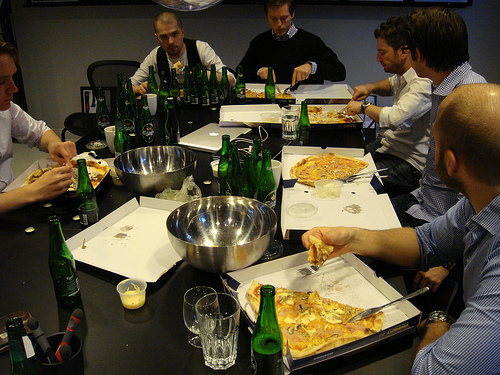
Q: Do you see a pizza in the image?
A: Yes, there is a pizza.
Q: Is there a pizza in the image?
A: Yes, there is a pizza.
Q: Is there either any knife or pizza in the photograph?
A: Yes, there is a pizza.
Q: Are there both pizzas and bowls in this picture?
A: Yes, there are both a pizza and a bowl.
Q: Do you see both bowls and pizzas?
A: Yes, there are both a pizza and a bowl.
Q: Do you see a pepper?
A: No, there are no peppers.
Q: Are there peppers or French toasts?
A: No, there are no peppers or French toasts.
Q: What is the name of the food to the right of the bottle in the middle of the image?
A: The food is a pizza.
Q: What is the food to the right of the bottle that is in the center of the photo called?
A: The food is a pizza.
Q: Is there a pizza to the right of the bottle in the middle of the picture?
A: Yes, there is a pizza to the right of the bottle.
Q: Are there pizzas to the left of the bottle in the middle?
A: No, the pizza is to the right of the bottle.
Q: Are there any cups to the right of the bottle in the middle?
A: No, there is a pizza to the right of the bottle.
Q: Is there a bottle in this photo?
A: Yes, there is a bottle.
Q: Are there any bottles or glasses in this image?
A: Yes, there is a bottle.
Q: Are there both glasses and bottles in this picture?
A: Yes, there are both a bottle and glasses.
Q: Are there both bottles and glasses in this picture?
A: Yes, there are both a bottle and glasses.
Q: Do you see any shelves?
A: No, there are no shelves.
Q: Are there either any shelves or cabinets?
A: No, there are no shelves or cabinets.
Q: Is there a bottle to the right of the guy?
A: Yes, there is a bottle to the right of the guy.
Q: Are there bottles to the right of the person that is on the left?
A: Yes, there is a bottle to the right of the guy.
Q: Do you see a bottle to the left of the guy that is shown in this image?
A: No, the bottle is to the right of the guy.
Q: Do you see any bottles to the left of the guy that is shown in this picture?
A: No, the bottle is to the right of the guy.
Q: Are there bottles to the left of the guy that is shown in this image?
A: No, the bottle is to the right of the guy.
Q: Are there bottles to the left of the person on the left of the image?
A: No, the bottle is to the right of the guy.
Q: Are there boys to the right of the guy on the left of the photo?
A: No, there is a bottle to the right of the guy.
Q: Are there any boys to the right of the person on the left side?
A: No, there is a bottle to the right of the guy.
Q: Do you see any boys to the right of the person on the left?
A: No, there is a bottle to the right of the guy.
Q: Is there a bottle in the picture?
A: Yes, there is a bottle.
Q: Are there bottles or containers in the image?
A: Yes, there is a bottle.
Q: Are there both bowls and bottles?
A: Yes, there are both a bottle and a bowl.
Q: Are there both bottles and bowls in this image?
A: Yes, there are both a bottle and a bowl.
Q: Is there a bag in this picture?
A: No, there are no bags.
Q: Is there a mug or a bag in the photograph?
A: No, there are no bags or mugs.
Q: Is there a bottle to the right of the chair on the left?
A: Yes, there is a bottle to the right of the chair.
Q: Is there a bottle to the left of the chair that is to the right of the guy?
A: No, the bottle is to the right of the chair.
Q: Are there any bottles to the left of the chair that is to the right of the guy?
A: No, the bottle is to the right of the chair.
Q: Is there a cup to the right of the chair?
A: No, there is a bottle to the right of the chair.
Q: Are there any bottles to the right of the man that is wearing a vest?
A: Yes, there is a bottle to the right of the man.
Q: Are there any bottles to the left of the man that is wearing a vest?
A: No, the bottle is to the right of the man.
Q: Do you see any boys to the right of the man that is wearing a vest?
A: No, there is a bottle to the right of the man.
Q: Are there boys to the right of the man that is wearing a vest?
A: No, there is a bottle to the right of the man.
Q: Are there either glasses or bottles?
A: Yes, there is a bottle.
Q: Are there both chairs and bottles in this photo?
A: Yes, there are both a bottle and a chair.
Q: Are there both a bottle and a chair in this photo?
A: Yes, there are both a bottle and a chair.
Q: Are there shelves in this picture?
A: No, there are no shelves.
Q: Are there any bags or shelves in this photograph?
A: No, there are no shelves or bags.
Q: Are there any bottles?
A: Yes, there is a bottle.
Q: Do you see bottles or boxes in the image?
A: Yes, there is a bottle.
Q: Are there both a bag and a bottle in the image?
A: No, there is a bottle but no bags.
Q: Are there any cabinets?
A: No, there are no cabinets.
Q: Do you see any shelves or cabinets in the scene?
A: No, there are no cabinets or shelves.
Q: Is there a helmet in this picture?
A: No, there are no helmets.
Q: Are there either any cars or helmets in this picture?
A: No, there are no helmets or cars.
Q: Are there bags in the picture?
A: No, there are no bags.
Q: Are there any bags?
A: No, there are no bags.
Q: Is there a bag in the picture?
A: No, there are no bags.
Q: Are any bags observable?
A: No, there are no bags.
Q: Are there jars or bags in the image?
A: No, there are no bags or jars.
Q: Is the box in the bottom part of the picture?
A: Yes, the box is in the bottom of the image.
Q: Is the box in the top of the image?
A: No, the box is in the bottom of the image.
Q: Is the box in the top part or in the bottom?
A: The box is in the bottom of the image.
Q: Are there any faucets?
A: No, there are no faucets.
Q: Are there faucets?
A: No, there are no faucets.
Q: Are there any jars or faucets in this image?
A: No, there are no faucets or jars.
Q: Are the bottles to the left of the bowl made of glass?
A: Yes, the bottles are made of glass.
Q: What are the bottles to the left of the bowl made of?
A: The bottles are made of glass.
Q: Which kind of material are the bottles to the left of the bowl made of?
A: The bottles are made of glass.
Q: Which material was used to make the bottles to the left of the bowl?
A: The bottles are made of glass.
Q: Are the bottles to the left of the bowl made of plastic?
A: No, the bottles are made of glass.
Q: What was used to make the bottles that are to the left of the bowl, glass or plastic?
A: The bottles are made of glass.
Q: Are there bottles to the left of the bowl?
A: Yes, there are bottles to the left of the bowl.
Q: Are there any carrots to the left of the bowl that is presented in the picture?
A: No, there are bottles to the left of the bowl.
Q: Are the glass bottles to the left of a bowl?
A: Yes, the bottles are to the left of a bowl.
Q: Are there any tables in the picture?
A: Yes, there is a table.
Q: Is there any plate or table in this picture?
A: Yes, there is a table.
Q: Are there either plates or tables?
A: Yes, there is a table.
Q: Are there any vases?
A: No, there are no vases.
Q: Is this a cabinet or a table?
A: This is a table.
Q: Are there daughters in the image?
A: No, there are no daughters.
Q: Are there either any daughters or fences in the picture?
A: No, there are no daughters or fences.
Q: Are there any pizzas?
A: Yes, there is a pizza.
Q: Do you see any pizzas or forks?
A: Yes, there is a pizza.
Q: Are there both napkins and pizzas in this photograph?
A: No, there is a pizza but no napkins.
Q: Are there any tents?
A: No, there are no tents.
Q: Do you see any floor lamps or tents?
A: No, there are no tents or floor lamps.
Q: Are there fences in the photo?
A: No, there are no fences.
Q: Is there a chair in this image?
A: Yes, there is a chair.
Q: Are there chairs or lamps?
A: Yes, there is a chair.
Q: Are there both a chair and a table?
A: Yes, there are both a chair and a table.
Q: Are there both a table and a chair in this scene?
A: Yes, there are both a chair and a table.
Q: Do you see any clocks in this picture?
A: No, there are no clocks.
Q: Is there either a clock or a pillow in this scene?
A: No, there are no clocks or pillows.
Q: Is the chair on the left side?
A: Yes, the chair is on the left of the image.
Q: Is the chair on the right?
A: No, the chair is on the left of the image.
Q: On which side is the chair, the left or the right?
A: The chair is on the left of the image.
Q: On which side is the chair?
A: The chair is on the left of the image.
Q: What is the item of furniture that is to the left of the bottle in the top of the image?
A: The piece of furniture is a chair.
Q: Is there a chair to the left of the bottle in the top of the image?
A: Yes, there is a chair to the left of the bottle.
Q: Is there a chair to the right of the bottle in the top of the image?
A: No, the chair is to the left of the bottle.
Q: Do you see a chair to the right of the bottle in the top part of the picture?
A: No, the chair is to the left of the bottle.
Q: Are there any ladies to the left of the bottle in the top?
A: No, there is a chair to the left of the bottle.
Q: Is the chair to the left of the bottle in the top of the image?
A: Yes, the chair is to the left of the bottle.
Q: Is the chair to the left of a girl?
A: No, the chair is to the left of the bottle.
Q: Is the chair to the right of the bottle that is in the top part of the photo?
A: No, the chair is to the left of the bottle.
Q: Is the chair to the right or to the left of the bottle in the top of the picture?
A: The chair is to the left of the bottle.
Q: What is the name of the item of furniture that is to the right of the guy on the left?
A: The piece of furniture is a chair.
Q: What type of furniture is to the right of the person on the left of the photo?
A: The piece of furniture is a chair.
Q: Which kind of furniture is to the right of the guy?
A: The piece of furniture is a chair.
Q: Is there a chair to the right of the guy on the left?
A: Yes, there is a chair to the right of the guy.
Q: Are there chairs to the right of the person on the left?
A: Yes, there is a chair to the right of the guy.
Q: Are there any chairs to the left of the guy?
A: No, the chair is to the right of the guy.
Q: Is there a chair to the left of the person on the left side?
A: No, the chair is to the right of the guy.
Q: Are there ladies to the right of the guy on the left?
A: No, there is a chair to the right of the guy.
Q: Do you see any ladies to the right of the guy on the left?
A: No, there is a chair to the right of the guy.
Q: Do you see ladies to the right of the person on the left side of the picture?
A: No, there is a chair to the right of the guy.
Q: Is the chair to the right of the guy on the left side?
A: Yes, the chair is to the right of the guy.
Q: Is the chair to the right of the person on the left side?
A: Yes, the chair is to the right of the guy.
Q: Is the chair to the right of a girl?
A: No, the chair is to the right of the guy.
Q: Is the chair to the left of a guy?
A: No, the chair is to the right of a guy.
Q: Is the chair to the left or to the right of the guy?
A: The chair is to the right of the guy.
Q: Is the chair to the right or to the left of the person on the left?
A: The chair is to the right of the guy.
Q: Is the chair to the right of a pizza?
A: No, the chair is to the left of a pizza.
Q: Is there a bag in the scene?
A: No, there are no bags.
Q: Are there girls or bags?
A: No, there are no bags or girls.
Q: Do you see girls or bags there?
A: No, there are no bags or girls.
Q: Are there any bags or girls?
A: No, there are no bags or girls.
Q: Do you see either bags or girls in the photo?
A: No, there are no bags or girls.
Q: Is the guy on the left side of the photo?
A: Yes, the guy is on the left of the image.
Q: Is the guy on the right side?
A: No, the guy is on the left of the image.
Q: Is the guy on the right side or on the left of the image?
A: The guy is on the left of the image.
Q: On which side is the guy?
A: The guy is on the left of the image.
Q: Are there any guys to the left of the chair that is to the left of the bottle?
A: Yes, there is a guy to the left of the chair.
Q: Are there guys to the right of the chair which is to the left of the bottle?
A: No, the guy is to the left of the chair.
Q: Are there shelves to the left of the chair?
A: No, there is a guy to the left of the chair.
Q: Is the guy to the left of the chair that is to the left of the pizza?
A: Yes, the guy is to the left of the chair.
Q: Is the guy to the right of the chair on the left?
A: No, the guy is to the left of the chair.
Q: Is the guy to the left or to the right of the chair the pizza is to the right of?
A: The guy is to the left of the chair.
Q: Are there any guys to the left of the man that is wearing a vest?
A: Yes, there is a guy to the left of the man.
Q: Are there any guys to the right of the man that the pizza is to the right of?
A: No, the guy is to the left of the man.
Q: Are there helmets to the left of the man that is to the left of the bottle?
A: No, there is a guy to the left of the man.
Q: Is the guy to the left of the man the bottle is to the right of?
A: Yes, the guy is to the left of the man.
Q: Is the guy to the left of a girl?
A: No, the guy is to the left of the man.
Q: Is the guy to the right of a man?
A: No, the guy is to the left of a man.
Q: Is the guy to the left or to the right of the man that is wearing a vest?
A: The guy is to the left of the man.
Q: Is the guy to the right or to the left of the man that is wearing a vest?
A: The guy is to the left of the man.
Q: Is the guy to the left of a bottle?
A: Yes, the guy is to the left of a bottle.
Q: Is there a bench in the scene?
A: No, there are no benches.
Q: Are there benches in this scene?
A: No, there are no benches.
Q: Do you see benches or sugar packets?
A: No, there are no benches or sugar packets.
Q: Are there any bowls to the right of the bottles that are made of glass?
A: Yes, there is a bowl to the right of the bottles.